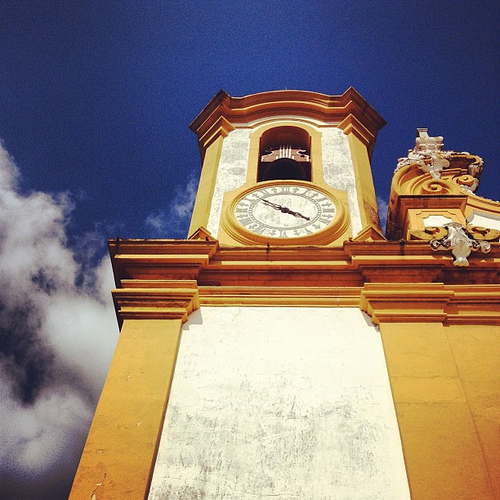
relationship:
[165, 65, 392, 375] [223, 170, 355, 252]
tower has clock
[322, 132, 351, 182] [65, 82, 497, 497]
design on tower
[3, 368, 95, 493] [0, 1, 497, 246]
cloud in sky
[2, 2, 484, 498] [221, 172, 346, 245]
photo has clock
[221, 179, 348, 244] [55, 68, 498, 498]
clock on building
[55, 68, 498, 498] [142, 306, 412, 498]
building has wall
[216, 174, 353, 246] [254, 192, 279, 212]
clock has clock arm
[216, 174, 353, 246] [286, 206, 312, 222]
clock has clock arm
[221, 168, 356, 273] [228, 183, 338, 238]
clock has clock interior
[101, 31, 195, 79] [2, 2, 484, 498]
skies in photo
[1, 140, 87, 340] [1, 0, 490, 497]
cloud in sky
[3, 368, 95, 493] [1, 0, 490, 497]
cloud in sky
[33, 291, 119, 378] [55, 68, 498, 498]
cloud above building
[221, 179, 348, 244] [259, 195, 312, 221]
clock has clock hands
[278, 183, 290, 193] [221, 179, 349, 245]
roman numeral on clock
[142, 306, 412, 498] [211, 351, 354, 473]
wall has space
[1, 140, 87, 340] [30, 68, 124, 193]
cloud in sky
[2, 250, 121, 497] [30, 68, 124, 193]
cloud in sky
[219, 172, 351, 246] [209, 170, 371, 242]
roman numerals on clock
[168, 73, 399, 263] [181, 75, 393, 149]
clock tower has top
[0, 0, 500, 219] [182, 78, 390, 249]
skies above tower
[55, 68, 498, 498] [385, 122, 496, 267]
building has achitecture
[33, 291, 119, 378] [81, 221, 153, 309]
cloud on building corner